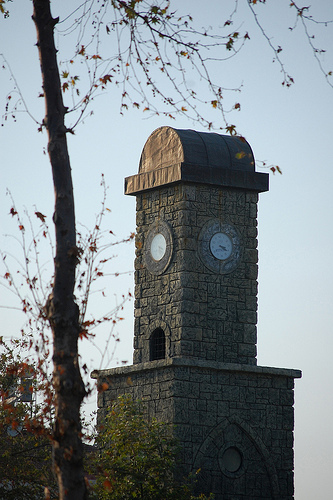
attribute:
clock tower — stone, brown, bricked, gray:
[83, 117, 305, 497]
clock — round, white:
[207, 233, 233, 262]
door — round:
[145, 321, 173, 361]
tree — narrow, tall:
[18, 6, 104, 499]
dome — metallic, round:
[117, 119, 274, 196]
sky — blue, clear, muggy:
[1, 1, 328, 499]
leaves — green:
[91, 393, 202, 499]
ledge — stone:
[90, 354, 305, 390]